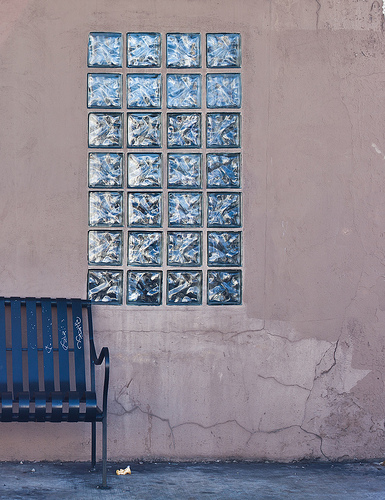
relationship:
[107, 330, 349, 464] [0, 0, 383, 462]
crack in wall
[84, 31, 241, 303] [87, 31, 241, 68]
window on row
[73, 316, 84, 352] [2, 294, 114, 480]
marking on bench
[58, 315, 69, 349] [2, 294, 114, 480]
marking on bench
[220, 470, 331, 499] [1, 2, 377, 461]
sidewalk next building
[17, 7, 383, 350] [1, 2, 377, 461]
wall on building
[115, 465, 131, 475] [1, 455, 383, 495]
piece litter on sidewalk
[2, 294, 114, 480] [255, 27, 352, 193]
bench next wall